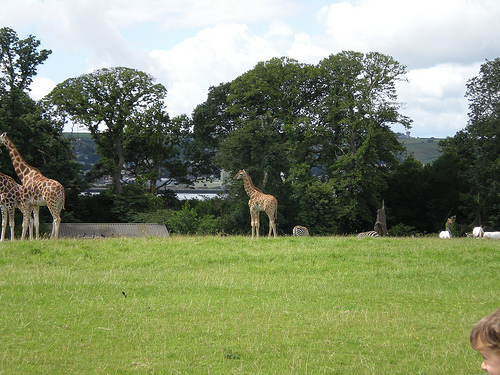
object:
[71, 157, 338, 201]
building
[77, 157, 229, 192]
roof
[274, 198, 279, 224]
tail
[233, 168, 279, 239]
giraffe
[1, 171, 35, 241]
giraffe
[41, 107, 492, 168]
field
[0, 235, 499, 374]
grass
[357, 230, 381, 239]
zebra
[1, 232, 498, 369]
field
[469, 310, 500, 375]
head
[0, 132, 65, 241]
giraffe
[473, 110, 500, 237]
tree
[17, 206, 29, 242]
leg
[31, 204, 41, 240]
leg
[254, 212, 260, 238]
leg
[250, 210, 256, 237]
leg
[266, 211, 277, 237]
giraffe leg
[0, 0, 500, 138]
sky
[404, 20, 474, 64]
clouds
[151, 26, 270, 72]
clouds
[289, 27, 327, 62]
clouds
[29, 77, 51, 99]
clouds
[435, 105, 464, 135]
clouds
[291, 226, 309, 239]
zebra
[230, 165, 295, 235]
giraffe tree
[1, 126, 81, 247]
giraffe tree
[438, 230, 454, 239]
white animals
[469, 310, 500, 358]
hair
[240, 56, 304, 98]
trees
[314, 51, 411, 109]
trees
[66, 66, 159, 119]
trees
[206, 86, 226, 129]
trees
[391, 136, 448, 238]
trees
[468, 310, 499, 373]
boy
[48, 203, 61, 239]
leg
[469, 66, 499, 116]
tree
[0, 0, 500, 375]
landscape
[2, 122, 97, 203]
background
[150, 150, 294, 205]
background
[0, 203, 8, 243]
legs